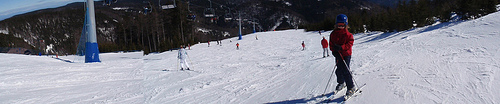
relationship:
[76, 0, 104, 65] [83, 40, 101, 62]
pole has blue trim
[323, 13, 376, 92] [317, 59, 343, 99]
boy holding ski pole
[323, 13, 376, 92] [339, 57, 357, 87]
boy holding ski pole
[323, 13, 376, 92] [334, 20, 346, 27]
boy wearing sunglasses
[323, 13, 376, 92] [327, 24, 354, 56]
boy wearing jacket.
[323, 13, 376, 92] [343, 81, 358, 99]
boy wearing boot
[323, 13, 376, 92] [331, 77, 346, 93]
boy wearing boot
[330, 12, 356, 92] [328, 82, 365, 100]
boy standing on ski skates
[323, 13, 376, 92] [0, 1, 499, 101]
boy visitting ski resort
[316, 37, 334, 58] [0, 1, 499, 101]
person visitting ski resort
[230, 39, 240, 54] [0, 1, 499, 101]
person visitting ski resort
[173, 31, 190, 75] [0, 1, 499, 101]
person visitting ski resort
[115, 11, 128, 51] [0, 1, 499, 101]
tree lining ski resort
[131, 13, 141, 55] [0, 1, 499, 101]
tree lining ski resort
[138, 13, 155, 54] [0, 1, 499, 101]
tree lining ski resort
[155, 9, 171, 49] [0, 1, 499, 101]
tree lining ski resort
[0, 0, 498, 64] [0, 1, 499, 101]
mountains can be seen from ski resort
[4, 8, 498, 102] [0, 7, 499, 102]
snow covering ground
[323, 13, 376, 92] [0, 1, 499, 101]
boy skiing at ski resort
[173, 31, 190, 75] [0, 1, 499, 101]
person skiing at ski resort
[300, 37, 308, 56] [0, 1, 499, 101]
person skiing at ski resort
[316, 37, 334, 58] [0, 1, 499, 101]
person skiing at ski resort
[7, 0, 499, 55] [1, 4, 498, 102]
trees surround photo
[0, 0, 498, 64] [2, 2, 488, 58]
mountains are in background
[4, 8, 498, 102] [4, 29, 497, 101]
snow covering ground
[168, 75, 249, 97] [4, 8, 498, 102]
track in snow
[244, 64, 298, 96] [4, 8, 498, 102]
track in snow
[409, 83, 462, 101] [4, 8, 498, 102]
track in snow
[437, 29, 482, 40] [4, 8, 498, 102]
track in snow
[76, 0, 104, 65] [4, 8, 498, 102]
pole in snow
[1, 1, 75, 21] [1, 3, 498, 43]
sky in background